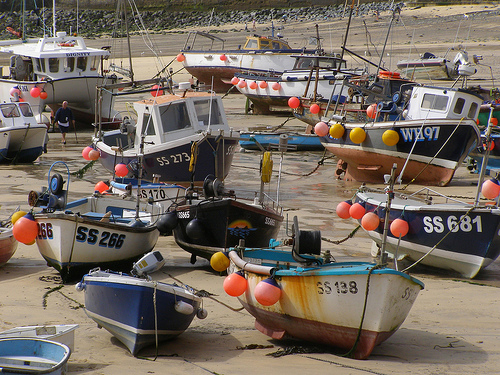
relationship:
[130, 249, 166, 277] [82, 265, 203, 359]
motor on boat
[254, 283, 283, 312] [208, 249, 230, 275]
buoy next to buoy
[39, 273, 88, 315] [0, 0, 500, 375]
line on ground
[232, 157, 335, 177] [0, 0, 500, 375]
rope on ground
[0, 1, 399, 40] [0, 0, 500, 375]
grass behind ground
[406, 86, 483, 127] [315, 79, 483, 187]
cabin on boat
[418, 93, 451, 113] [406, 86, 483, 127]
window on cabin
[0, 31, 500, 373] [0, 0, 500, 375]
boats in ground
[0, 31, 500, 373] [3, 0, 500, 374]
boats on beach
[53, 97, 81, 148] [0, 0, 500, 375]
person on ground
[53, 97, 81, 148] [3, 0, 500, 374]
person on beach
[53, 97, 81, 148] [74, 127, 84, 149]
person carrying stick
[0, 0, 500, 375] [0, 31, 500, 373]
ground under boats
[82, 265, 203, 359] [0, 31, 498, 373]
boat on ground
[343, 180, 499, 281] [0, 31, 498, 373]
boat on ground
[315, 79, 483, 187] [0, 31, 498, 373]
boat on ground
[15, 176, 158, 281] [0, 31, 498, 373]
boat on ground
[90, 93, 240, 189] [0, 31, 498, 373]
boat on ground